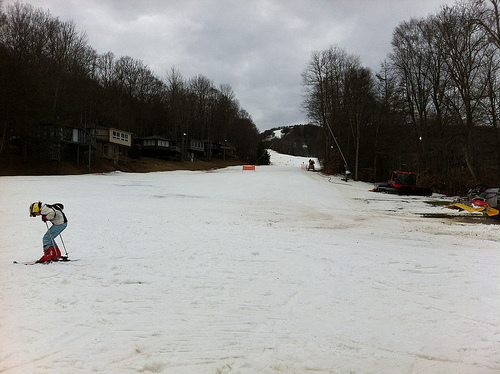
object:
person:
[28, 200, 68, 263]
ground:
[248, 166, 324, 250]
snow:
[323, 227, 407, 310]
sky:
[242, 5, 304, 75]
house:
[78, 115, 135, 166]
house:
[136, 131, 184, 161]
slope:
[265, 145, 295, 165]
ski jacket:
[37, 201, 68, 226]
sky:
[144, 2, 242, 58]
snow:
[85, 194, 225, 348]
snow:
[214, 171, 313, 216]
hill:
[260, 122, 325, 157]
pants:
[42, 222, 68, 255]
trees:
[296, 43, 378, 181]